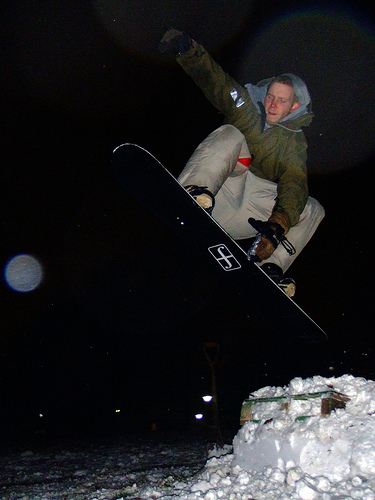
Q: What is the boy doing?
A: Snowboarding.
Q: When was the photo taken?
A: At night time.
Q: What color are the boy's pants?
A: Khaki.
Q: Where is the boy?
A: On snow.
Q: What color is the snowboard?
A: Black.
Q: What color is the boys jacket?
A: Green.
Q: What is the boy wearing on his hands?
A: Gloves.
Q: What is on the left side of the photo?
A: A moon.